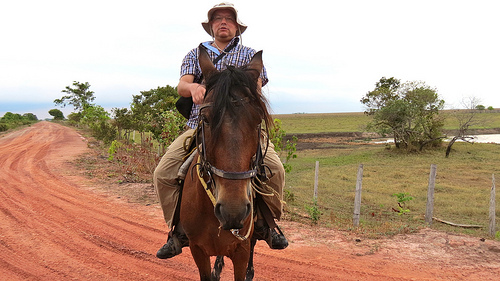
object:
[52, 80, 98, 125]
tree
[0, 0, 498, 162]
background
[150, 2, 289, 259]
man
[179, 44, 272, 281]
horse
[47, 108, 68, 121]
trees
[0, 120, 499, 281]
path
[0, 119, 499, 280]
dirt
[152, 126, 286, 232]
pants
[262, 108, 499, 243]
grass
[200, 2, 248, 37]
hat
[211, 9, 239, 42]
head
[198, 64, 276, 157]
hair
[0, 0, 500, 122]
sky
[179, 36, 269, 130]
shirt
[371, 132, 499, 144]
water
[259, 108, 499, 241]
field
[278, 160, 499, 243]
fence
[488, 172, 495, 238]
wood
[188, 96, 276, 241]
reins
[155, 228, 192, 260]
foot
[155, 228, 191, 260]
shoe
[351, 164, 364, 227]
post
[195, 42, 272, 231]
head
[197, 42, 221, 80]
ear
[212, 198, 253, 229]
nose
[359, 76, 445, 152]
tree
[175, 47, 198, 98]
arm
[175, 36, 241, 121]
sack